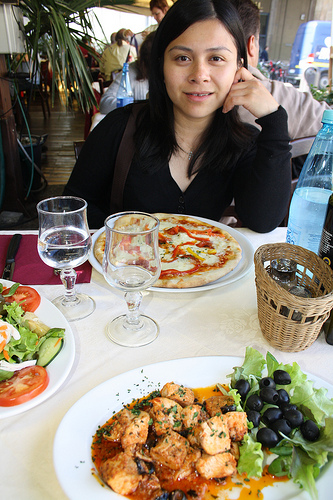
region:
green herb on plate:
[110, 376, 153, 398]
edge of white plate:
[53, 406, 118, 451]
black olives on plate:
[233, 362, 322, 452]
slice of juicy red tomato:
[11, 372, 56, 401]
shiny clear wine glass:
[106, 206, 172, 343]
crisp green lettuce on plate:
[241, 347, 286, 368]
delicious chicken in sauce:
[155, 437, 224, 474]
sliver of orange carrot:
[45, 332, 76, 357]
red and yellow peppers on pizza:
[167, 221, 214, 273]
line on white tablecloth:
[87, 343, 123, 369]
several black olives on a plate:
[232, 365, 327, 467]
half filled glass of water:
[29, 194, 96, 320]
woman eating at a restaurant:
[63, 2, 301, 299]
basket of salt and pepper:
[254, 241, 332, 343]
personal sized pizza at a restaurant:
[92, 209, 257, 296]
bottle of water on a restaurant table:
[280, 105, 331, 260]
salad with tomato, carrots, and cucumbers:
[0, 267, 75, 407]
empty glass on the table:
[99, 211, 162, 350]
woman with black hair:
[135, 1, 259, 174]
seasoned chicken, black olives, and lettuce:
[78, 371, 318, 494]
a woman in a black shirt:
[100, 22, 299, 236]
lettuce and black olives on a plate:
[225, 355, 331, 476]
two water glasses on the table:
[25, 195, 211, 338]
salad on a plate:
[2, 276, 98, 423]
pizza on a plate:
[85, 204, 263, 315]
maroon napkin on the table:
[5, 237, 161, 324]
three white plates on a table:
[15, 238, 270, 434]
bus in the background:
[285, 12, 331, 97]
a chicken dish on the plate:
[81, 371, 289, 498]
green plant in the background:
[14, 6, 115, 110]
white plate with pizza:
[90, 206, 254, 297]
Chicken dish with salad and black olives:
[50, 351, 331, 498]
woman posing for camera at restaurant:
[55, 1, 296, 232]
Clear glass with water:
[31, 194, 101, 326]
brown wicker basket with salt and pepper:
[251, 233, 331, 354]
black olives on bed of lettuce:
[237, 366, 320, 444]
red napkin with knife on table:
[1, 231, 36, 286]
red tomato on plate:
[0, 364, 52, 406]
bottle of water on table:
[285, 111, 332, 265]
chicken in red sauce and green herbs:
[96, 379, 245, 495]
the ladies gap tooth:
[184, 87, 209, 104]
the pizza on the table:
[99, 217, 206, 304]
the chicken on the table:
[110, 405, 234, 475]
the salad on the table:
[1, 294, 73, 399]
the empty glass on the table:
[101, 219, 187, 341]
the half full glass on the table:
[35, 200, 106, 323]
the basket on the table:
[248, 238, 322, 351]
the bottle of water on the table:
[283, 112, 324, 263]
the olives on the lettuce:
[251, 383, 302, 454]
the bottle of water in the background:
[114, 57, 140, 105]